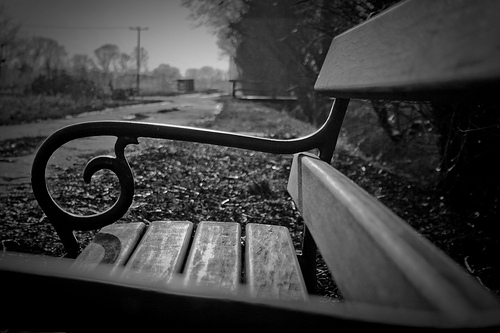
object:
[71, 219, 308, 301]
boards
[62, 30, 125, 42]
sky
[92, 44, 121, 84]
tree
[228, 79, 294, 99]
bridge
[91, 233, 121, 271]
shadow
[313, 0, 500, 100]
slat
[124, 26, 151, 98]
post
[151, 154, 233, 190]
leaves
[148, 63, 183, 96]
trees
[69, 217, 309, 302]
seat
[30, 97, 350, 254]
armrest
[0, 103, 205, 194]
sidewalk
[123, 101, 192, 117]
dirt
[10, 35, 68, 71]
trees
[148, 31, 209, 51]
sky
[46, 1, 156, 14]
sky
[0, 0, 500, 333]
iron/wood bench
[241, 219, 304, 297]
plank